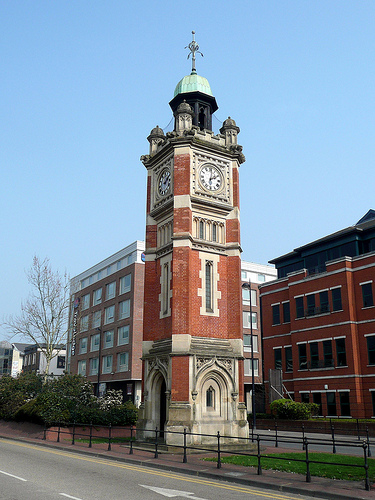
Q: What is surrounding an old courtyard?
A: A black metal fence.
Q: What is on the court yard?
A: An old clock tower.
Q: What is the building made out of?
A: Brick.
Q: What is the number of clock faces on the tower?
A: Two.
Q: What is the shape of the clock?
A: A circle.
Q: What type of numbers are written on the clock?
A: Roman numerals.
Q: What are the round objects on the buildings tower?
A: Clocks.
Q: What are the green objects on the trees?
A: Leaves.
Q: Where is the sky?
A: Above the building.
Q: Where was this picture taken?
A: In a city.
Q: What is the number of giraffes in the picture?
A: Zero.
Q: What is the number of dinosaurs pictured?
A: Zero.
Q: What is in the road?
A: Building.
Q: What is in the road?
A: Bricks.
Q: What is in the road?
A: Building.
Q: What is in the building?
A: Tower.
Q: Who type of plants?
A: Bushes.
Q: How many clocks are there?
A: 2.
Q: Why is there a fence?
A: To mark boundary.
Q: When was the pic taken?
A: During the day.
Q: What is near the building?
A: A fence.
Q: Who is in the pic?
A: No one.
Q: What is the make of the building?
A: Bricks.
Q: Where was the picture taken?
A: Outside of a brick building.